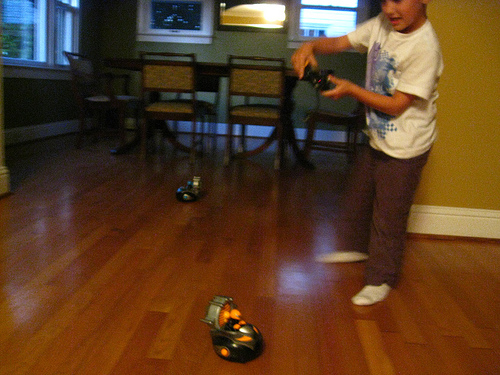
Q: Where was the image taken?
A: It was taken at the living room.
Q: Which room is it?
A: It is a living room.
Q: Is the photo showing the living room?
A: Yes, it is showing the living room.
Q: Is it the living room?
A: Yes, it is the living room.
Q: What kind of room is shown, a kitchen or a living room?
A: It is a living room.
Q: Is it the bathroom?
A: No, it is the living room.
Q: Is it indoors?
A: Yes, it is indoors.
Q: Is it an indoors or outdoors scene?
A: It is indoors.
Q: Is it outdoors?
A: No, it is indoors.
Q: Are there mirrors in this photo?
A: Yes, there is a mirror.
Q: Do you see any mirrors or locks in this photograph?
A: Yes, there is a mirror.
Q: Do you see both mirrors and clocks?
A: No, there is a mirror but no clocks.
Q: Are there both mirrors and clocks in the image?
A: No, there is a mirror but no clocks.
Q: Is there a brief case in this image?
A: No, there are no briefcases.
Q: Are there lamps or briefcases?
A: No, there are no briefcases or lamps.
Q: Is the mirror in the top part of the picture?
A: Yes, the mirror is in the top of the image.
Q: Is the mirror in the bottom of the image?
A: No, the mirror is in the top of the image.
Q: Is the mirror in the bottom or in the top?
A: The mirror is in the top of the image.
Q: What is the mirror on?
A: The mirror is on the wall.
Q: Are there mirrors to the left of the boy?
A: Yes, there is a mirror to the left of the boy.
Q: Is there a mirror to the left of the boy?
A: Yes, there is a mirror to the left of the boy.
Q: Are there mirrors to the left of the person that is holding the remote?
A: Yes, there is a mirror to the left of the boy.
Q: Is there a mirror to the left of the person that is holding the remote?
A: Yes, there is a mirror to the left of the boy.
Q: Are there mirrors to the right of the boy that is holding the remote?
A: No, the mirror is to the left of the boy.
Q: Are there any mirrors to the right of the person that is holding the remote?
A: No, the mirror is to the left of the boy.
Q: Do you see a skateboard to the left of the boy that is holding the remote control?
A: No, there is a mirror to the left of the boy.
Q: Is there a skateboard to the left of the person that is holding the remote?
A: No, there is a mirror to the left of the boy.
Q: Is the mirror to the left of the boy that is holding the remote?
A: Yes, the mirror is to the left of the boy.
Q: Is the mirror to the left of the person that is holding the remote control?
A: Yes, the mirror is to the left of the boy.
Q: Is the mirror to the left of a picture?
A: No, the mirror is to the left of the boy.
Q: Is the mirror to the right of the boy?
A: No, the mirror is to the left of the boy.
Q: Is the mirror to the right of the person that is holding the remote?
A: No, the mirror is to the left of the boy.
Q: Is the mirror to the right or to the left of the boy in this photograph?
A: The mirror is to the left of the boy.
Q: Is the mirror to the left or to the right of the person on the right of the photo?
A: The mirror is to the left of the boy.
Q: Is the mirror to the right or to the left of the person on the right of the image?
A: The mirror is to the left of the boy.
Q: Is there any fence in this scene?
A: No, there are no fences.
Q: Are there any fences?
A: No, there are no fences.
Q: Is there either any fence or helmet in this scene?
A: No, there are no fences or helmets.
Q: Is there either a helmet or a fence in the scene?
A: No, there are no fences or helmets.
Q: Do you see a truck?
A: No, there are no trucks.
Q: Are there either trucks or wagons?
A: No, there are no trucks or wagons.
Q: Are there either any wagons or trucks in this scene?
A: No, there are no trucks or wagons.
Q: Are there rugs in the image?
A: No, there are no rugs.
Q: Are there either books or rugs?
A: No, there are no rugs or books.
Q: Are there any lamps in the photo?
A: No, there are no lamps.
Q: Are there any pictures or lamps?
A: No, there are no lamps or pictures.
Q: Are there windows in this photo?
A: Yes, there is a window.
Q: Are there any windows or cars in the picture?
A: Yes, there is a window.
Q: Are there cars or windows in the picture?
A: Yes, there is a window.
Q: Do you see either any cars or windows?
A: Yes, there is a window.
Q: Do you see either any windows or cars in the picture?
A: Yes, there is a window.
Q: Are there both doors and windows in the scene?
A: No, there is a window but no doors.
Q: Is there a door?
A: No, there are no doors.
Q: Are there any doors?
A: No, there are no doors.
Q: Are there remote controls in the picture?
A: Yes, there is a remote control.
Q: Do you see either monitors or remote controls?
A: Yes, there is a remote control.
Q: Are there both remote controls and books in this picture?
A: No, there is a remote control but no books.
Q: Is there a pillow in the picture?
A: No, there are no pillows.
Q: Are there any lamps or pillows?
A: No, there are no pillows or lamps.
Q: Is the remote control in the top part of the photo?
A: Yes, the remote control is in the top of the image.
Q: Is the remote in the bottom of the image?
A: No, the remote is in the top of the image.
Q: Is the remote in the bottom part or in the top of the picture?
A: The remote is in the top of the image.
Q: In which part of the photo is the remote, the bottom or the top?
A: The remote is in the top of the image.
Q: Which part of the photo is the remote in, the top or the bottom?
A: The remote is in the top of the image.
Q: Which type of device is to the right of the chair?
A: The device is a remote control.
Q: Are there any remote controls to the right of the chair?
A: Yes, there is a remote control to the right of the chair.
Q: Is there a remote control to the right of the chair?
A: Yes, there is a remote control to the right of the chair.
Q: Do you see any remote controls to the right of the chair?
A: Yes, there is a remote control to the right of the chair.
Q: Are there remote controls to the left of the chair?
A: No, the remote control is to the right of the chair.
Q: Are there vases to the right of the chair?
A: No, there is a remote control to the right of the chair.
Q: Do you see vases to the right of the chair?
A: No, there is a remote control to the right of the chair.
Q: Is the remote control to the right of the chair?
A: Yes, the remote control is to the right of the chair.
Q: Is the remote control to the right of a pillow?
A: No, the remote control is to the right of the chair.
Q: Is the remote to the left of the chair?
A: No, the remote is to the right of the chair.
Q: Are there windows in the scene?
A: Yes, there is a window.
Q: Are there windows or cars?
A: Yes, there is a window.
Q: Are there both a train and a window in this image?
A: No, there is a window but no trains.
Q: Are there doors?
A: No, there are no doors.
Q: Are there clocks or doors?
A: No, there are no doors or clocks.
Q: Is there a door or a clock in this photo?
A: No, there are no doors or clocks.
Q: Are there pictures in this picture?
A: No, there are no pictures.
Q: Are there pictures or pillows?
A: No, there are no pictures or pillows.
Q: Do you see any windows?
A: Yes, there is a window.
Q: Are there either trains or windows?
A: Yes, there is a window.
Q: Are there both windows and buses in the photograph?
A: No, there is a window but no buses.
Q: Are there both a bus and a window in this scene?
A: No, there is a window but no buses.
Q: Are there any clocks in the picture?
A: No, there are no clocks.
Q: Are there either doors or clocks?
A: No, there are no clocks or doors.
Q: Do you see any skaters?
A: No, there are no skaters.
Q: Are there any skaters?
A: No, there are no skaters.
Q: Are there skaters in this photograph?
A: No, there are no skaters.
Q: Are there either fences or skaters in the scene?
A: No, there are no skaters or fences.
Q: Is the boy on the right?
A: Yes, the boy is on the right of the image.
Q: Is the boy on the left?
A: No, the boy is on the right of the image.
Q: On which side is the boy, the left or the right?
A: The boy is on the right of the image.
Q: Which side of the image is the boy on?
A: The boy is on the right of the image.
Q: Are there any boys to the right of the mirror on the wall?
A: Yes, there is a boy to the right of the mirror.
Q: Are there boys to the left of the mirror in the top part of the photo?
A: No, the boy is to the right of the mirror.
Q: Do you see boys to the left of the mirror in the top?
A: No, the boy is to the right of the mirror.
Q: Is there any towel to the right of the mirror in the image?
A: No, there is a boy to the right of the mirror.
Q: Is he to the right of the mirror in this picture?
A: Yes, the boy is to the right of the mirror.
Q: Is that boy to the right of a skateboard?
A: No, the boy is to the right of the mirror.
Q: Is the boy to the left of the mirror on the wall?
A: No, the boy is to the right of the mirror.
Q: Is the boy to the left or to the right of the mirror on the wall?
A: The boy is to the right of the mirror.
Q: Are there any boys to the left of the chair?
A: No, the boy is to the right of the chair.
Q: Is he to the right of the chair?
A: Yes, the boy is to the right of the chair.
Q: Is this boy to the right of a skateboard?
A: No, the boy is to the right of the chair.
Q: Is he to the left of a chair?
A: No, the boy is to the right of a chair.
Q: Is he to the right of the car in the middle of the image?
A: Yes, the boy is to the right of the car.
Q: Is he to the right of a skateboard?
A: No, the boy is to the right of the car.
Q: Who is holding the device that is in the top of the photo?
A: The boy is holding the remote control.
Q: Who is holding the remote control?
A: The boy is holding the remote control.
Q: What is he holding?
A: The boy is holding the remote.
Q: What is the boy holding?
A: The boy is holding the remote.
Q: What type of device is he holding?
A: The boy is holding the remote control.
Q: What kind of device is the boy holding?
A: The boy is holding the remote control.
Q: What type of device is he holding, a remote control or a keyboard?
A: The boy is holding a remote control.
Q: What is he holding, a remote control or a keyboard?
A: The boy is holding a remote control.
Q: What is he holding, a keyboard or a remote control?
A: The boy is holding a remote control.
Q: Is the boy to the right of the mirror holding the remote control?
A: Yes, the boy is holding the remote control.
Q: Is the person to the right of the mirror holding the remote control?
A: Yes, the boy is holding the remote control.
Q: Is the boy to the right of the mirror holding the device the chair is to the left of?
A: Yes, the boy is holding the remote control.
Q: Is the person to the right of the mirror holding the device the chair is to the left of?
A: Yes, the boy is holding the remote control.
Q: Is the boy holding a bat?
A: No, the boy is holding the remote control.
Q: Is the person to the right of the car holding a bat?
A: No, the boy is holding the remote control.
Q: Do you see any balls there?
A: No, there are no balls.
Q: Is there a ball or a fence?
A: No, there are no balls or fences.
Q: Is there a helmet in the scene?
A: No, there are no helmets.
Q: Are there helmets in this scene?
A: No, there are no helmets.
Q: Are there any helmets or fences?
A: No, there are no helmets or fences.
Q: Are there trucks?
A: No, there are no trucks.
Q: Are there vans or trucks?
A: No, there are no trucks or vans.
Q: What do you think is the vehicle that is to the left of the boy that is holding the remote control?
A: The vehicle is a car.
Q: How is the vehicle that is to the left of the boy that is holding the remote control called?
A: The vehicle is a car.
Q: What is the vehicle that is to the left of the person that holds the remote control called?
A: The vehicle is a car.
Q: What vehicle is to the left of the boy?
A: The vehicle is a car.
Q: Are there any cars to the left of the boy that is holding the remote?
A: Yes, there is a car to the left of the boy.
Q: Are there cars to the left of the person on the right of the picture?
A: Yes, there is a car to the left of the boy.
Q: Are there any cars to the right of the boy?
A: No, the car is to the left of the boy.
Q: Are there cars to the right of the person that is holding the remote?
A: No, the car is to the left of the boy.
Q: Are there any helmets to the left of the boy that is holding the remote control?
A: No, there is a car to the left of the boy.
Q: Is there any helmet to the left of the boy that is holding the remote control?
A: No, there is a car to the left of the boy.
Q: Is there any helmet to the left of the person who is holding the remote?
A: No, there is a car to the left of the boy.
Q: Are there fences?
A: No, there are no fences.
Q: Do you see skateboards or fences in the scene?
A: No, there are no fences or skateboards.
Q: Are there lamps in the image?
A: No, there are no lamps.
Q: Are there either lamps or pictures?
A: No, there are no lamps or pictures.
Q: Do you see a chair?
A: Yes, there is a chair.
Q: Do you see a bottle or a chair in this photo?
A: Yes, there is a chair.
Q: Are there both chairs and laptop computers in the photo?
A: No, there is a chair but no laptops.